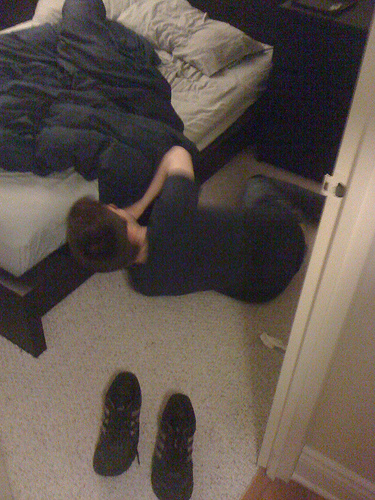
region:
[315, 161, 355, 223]
white painted door plate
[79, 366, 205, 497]
two black addis running shoes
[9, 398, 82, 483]
thick rough white carpet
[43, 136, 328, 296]
boy rolling on floor with blue shirt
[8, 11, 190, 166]
blue comforter on bed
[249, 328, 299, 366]
white and grey sock on floor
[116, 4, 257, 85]
light blue wrinkled pillow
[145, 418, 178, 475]
black and grey striped shoes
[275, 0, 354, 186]
black night stand with drawers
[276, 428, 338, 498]
white crown molding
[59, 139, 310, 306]
boy laying on floor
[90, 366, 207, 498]
a pair of sneakers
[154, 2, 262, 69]
wrinkled white pillowcase on bed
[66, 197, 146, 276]
back of boy's head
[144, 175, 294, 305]
dark short sleeved tee shirt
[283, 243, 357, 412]
frame of bedroom floor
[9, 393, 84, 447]
light colored bedroom carpet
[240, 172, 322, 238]
blue jeans on boy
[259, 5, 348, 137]
furniture next to bed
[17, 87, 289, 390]
Reaching under the bed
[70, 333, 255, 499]
Well worn sneakers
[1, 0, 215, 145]
Winter weight comforter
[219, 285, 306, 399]
Paper on the floor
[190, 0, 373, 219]
Table by side of bed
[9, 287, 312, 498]
Light color durable carpet.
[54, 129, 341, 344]
Wearing a blue shirt and blue jeans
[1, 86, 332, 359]
A platform bed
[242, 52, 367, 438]
An open doorway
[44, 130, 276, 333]
Wearing a short sleeve shirt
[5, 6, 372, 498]
photograph of a bed in a bedroom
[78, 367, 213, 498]
pair of sneakers on carpet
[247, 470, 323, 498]
wood floor outside bedroom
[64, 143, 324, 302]
man lying on floor by bed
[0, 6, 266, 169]
mattress and bed coverings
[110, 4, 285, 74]
pillow on top of bed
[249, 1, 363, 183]
nightstand on side of bed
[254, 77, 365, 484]
frame of door to bedroom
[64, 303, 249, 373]
beige carpet in bedroom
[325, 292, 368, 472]
beige painted wall in hallway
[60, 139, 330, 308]
young boy with short brown hair and blue shirt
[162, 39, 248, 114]
white sheet on the bed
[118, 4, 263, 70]
pillow in a white pillowcase on the right side of the bed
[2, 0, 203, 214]
Dark blanket lying on the bed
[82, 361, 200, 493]
pair of dark shoes with lighter stripes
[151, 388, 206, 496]
left shoe dark lighter stripes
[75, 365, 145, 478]
right shoe dark with lighter stripe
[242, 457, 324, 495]
wood flooring leading from the hallway into the bedroom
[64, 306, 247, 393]
light colored berber type carpet in the bedroom where the boy is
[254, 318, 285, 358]
piece of paper lying on the carpet floor between the boy and the wall